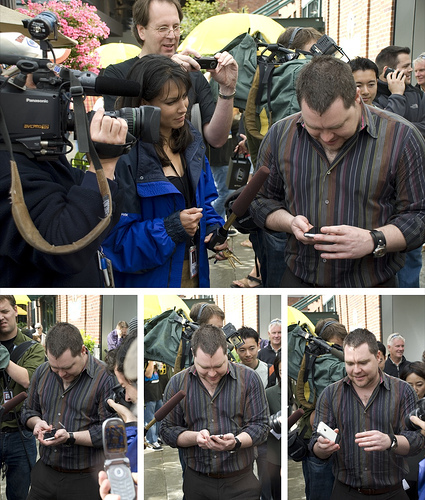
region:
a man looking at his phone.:
[203, 61, 423, 288]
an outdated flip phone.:
[88, 416, 143, 497]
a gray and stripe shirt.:
[158, 357, 275, 479]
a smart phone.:
[316, 416, 351, 447]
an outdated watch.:
[385, 423, 397, 455]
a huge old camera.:
[0, 9, 194, 191]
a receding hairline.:
[186, 322, 244, 357]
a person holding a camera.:
[187, 43, 235, 79]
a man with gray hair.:
[385, 327, 412, 361]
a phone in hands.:
[185, 417, 252, 467]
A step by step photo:
[5, 277, 424, 495]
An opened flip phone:
[82, 409, 151, 498]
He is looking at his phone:
[18, 321, 109, 496]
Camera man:
[142, 293, 258, 379]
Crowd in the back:
[100, 300, 386, 461]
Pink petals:
[14, 1, 118, 104]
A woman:
[90, 66, 244, 296]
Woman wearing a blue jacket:
[98, 111, 248, 297]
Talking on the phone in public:
[357, 18, 417, 93]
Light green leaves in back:
[138, 2, 286, 141]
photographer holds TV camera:
[0, 11, 160, 262]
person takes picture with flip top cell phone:
[54, 388, 137, 498]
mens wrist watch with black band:
[381, 424, 404, 461]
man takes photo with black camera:
[121, 3, 253, 91]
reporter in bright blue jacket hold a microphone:
[118, 52, 238, 282]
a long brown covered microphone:
[137, 369, 201, 435]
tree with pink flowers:
[11, 0, 115, 72]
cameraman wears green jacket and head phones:
[135, 293, 221, 404]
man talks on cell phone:
[367, 33, 413, 107]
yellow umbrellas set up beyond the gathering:
[82, 0, 292, 75]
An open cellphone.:
[91, 415, 137, 496]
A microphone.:
[209, 156, 275, 253]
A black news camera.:
[5, 9, 164, 208]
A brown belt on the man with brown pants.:
[176, 460, 264, 486]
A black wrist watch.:
[362, 221, 397, 267]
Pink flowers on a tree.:
[56, 1, 113, 70]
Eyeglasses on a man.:
[136, 17, 192, 43]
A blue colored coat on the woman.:
[96, 145, 235, 285]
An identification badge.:
[184, 241, 203, 279]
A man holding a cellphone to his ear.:
[373, 44, 419, 96]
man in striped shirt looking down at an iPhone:
[247, 55, 420, 284]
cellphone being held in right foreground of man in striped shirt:
[96, 413, 134, 494]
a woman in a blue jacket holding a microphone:
[119, 54, 264, 282]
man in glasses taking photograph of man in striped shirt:
[105, 0, 232, 137]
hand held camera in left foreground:
[0, 51, 157, 154]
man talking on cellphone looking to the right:
[374, 43, 419, 105]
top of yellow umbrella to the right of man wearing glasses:
[181, 7, 276, 51]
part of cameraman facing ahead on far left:
[0, 292, 40, 494]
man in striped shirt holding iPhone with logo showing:
[311, 418, 335, 454]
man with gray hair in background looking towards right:
[386, 330, 408, 377]